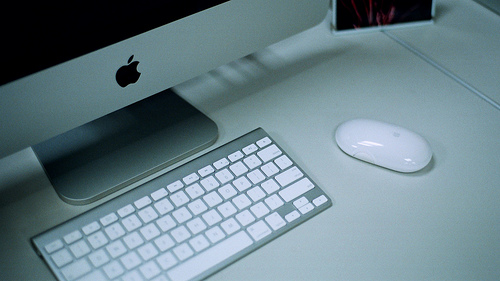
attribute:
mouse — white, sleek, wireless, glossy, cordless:
[334, 118, 433, 173]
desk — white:
[0, 1, 499, 280]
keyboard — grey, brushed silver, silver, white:
[31, 127, 332, 280]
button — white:
[256, 135, 272, 147]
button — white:
[274, 166, 305, 188]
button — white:
[215, 167, 234, 184]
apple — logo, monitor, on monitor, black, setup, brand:
[114, 54, 142, 88]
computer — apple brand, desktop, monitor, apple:
[0, 1, 331, 206]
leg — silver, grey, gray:
[32, 87, 219, 207]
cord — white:
[381, 28, 499, 109]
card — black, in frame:
[333, 0, 438, 34]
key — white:
[189, 199, 208, 213]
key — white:
[219, 201, 238, 217]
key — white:
[122, 215, 141, 230]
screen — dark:
[1, 2, 229, 89]